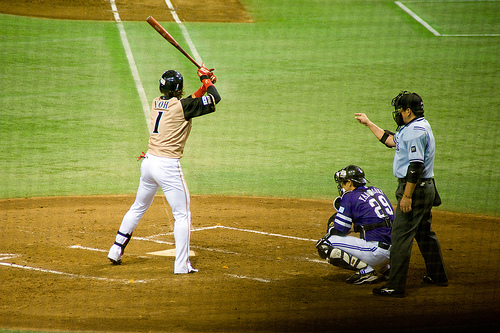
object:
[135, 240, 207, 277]
base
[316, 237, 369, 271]
guards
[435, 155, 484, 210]
ground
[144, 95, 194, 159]
back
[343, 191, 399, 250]
back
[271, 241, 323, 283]
ground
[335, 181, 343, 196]
mask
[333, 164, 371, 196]
helmet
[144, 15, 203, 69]
bat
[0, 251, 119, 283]
lines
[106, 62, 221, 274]
baseball player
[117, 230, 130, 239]
straps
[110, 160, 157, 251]
leg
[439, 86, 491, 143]
ground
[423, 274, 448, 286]
black shoe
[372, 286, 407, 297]
black shoe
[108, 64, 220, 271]
batter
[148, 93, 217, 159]
jersey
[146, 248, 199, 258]
home plate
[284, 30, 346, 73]
grass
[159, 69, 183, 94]
helmet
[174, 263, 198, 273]
foot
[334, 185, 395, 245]
jersey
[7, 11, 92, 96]
ground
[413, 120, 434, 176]
back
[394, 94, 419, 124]
head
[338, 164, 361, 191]
head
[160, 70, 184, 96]
head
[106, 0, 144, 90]
lines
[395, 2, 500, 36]
lines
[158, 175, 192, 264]
leg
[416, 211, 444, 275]
leg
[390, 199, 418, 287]
leg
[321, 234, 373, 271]
leg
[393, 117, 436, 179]
shirt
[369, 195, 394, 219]
number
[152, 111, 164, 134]
number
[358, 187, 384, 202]
surname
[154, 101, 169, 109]
surname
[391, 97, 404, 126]
mask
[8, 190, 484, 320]
dirt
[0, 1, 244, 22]
dirt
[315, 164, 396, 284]
baseball player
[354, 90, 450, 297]
pitcher